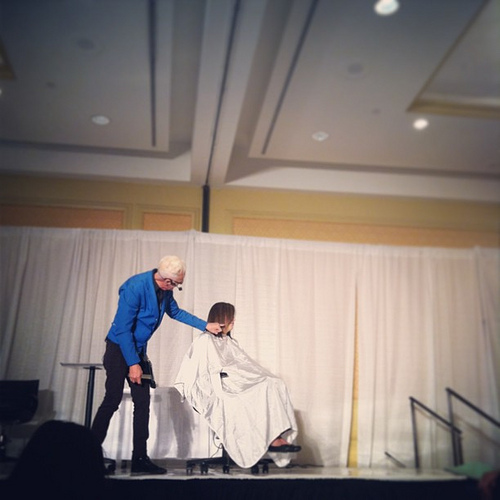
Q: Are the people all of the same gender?
A: No, they are both male and female.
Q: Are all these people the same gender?
A: No, they are both male and female.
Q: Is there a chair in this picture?
A: Yes, there is a chair.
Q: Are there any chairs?
A: Yes, there is a chair.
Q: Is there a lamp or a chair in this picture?
A: Yes, there is a chair.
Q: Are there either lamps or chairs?
A: Yes, there is a chair.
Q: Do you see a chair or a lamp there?
A: Yes, there is a chair.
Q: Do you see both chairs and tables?
A: Yes, there are both a chair and a table.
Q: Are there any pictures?
A: No, there are no pictures.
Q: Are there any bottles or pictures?
A: No, there are no pictures or bottles.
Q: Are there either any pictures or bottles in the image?
A: No, there are no pictures or bottles.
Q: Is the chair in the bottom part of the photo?
A: Yes, the chair is in the bottom of the image.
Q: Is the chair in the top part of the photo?
A: No, the chair is in the bottom of the image.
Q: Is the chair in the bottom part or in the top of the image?
A: The chair is in the bottom of the image.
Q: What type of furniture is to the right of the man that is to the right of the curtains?
A: The piece of furniture is a chair.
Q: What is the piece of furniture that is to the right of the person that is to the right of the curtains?
A: The piece of furniture is a chair.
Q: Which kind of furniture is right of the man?
A: The piece of furniture is a chair.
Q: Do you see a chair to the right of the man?
A: Yes, there is a chair to the right of the man.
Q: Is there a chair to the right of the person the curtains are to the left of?
A: Yes, there is a chair to the right of the man.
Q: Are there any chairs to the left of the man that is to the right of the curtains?
A: No, the chair is to the right of the man.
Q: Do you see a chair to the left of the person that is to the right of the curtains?
A: No, the chair is to the right of the man.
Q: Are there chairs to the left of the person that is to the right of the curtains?
A: No, the chair is to the right of the man.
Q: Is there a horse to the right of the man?
A: No, there is a chair to the right of the man.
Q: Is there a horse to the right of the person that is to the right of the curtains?
A: No, there is a chair to the right of the man.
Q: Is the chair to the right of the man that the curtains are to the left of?
A: Yes, the chair is to the right of the man.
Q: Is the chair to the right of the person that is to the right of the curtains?
A: Yes, the chair is to the right of the man.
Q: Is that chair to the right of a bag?
A: No, the chair is to the right of the man.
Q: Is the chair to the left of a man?
A: No, the chair is to the right of a man.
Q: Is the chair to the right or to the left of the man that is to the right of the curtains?
A: The chair is to the right of the man.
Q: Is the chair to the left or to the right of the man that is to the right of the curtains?
A: The chair is to the right of the man.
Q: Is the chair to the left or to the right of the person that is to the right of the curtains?
A: The chair is to the right of the man.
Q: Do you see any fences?
A: No, there are no fences.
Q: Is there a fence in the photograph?
A: No, there are no fences.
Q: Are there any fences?
A: No, there are no fences.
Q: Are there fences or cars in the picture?
A: No, there are no fences or cars.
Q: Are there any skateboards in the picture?
A: No, there are no skateboards.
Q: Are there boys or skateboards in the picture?
A: No, there are no skateboards or boys.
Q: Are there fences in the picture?
A: No, there are no fences.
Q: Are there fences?
A: No, there are no fences.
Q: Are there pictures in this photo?
A: No, there are no pictures.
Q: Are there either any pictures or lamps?
A: No, there are no pictures or lamps.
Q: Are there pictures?
A: No, there are no pictures.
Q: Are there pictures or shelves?
A: No, there are no pictures or shelves.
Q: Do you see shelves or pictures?
A: No, there are no pictures or shelves.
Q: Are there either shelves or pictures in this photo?
A: No, there are no pictures or shelves.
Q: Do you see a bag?
A: No, there are no bags.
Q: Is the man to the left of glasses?
A: No, the man is to the left of the draperies.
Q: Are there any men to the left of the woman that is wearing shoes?
A: Yes, there is a man to the left of the woman.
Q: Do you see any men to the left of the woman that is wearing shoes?
A: Yes, there is a man to the left of the woman.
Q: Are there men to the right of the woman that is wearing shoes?
A: No, the man is to the left of the woman.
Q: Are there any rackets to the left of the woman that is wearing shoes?
A: No, there is a man to the left of the woman.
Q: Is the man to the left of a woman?
A: Yes, the man is to the left of a woman.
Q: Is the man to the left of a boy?
A: No, the man is to the left of a woman.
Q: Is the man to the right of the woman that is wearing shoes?
A: No, the man is to the left of the woman.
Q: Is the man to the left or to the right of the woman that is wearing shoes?
A: The man is to the left of the woman.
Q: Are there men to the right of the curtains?
A: Yes, there is a man to the right of the curtains.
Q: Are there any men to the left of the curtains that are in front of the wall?
A: No, the man is to the right of the curtains.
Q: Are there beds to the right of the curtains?
A: No, there is a man to the right of the curtains.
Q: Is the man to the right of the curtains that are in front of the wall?
A: Yes, the man is to the right of the curtains.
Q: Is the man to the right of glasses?
A: No, the man is to the right of the curtains.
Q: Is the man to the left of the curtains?
A: No, the man is to the right of the curtains.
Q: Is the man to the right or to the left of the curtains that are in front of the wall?
A: The man is to the right of the curtains.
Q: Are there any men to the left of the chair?
A: Yes, there is a man to the left of the chair.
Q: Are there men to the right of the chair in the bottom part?
A: No, the man is to the left of the chair.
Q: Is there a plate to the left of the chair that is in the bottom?
A: No, there is a man to the left of the chair.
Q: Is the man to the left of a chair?
A: Yes, the man is to the left of a chair.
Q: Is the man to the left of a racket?
A: No, the man is to the left of a chair.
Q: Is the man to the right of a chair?
A: No, the man is to the left of a chair.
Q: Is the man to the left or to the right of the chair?
A: The man is to the left of the chair.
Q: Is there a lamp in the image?
A: No, there are no lamps.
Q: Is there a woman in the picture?
A: Yes, there is a woman.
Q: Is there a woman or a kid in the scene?
A: Yes, there is a woman.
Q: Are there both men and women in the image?
A: Yes, there are both a woman and a man.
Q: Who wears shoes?
A: The woman wears shoes.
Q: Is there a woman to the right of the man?
A: Yes, there is a woman to the right of the man.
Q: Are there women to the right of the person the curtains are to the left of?
A: Yes, there is a woman to the right of the man.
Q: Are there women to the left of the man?
A: No, the woman is to the right of the man.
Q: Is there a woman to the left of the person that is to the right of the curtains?
A: No, the woman is to the right of the man.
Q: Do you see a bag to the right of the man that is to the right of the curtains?
A: No, there is a woman to the right of the man.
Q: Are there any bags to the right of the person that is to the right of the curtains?
A: No, there is a woman to the right of the man.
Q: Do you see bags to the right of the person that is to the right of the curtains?
A: No, there is a woman to the right of the man.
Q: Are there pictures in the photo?
A: No, there are no pictures.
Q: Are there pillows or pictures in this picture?
A: No, there are no pictures or pillows.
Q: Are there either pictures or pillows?
A: No, there are no pictures or pillows.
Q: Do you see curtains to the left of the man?
A: Yes, there are curtains to the left of the man.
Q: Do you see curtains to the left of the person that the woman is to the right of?
A: Yes, there are curtains to the left of the man.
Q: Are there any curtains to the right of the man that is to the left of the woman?
A: No, the curtains are to the left of the man.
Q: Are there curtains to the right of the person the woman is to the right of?
A: No, the curtains are to the left of the man.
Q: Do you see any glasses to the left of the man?
A: No, there are curtains to the left of the man.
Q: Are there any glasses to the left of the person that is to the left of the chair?
A: No, there are curtains to the left of the man.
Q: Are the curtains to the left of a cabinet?
A: No, the curtains are to the left of a man.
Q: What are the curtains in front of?
A: The curtains are in front of the wall.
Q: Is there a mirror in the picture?
A: No, there are no mirrors.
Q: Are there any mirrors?
A: No, there are no mirrors.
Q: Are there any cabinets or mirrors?
A: No, there are no mirrors or cabinets.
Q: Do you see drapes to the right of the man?
A: Yes, there are drapes to the right of the man.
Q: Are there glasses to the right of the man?
A: No, there are drapes to the right of the man.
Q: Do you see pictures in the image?
A: No, there are no pictures.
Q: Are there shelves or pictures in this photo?
A: No, there are no pictures or shelves.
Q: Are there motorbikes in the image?
A: No, there are no motorbikes.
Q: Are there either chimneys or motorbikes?
A: No, there are no motorbikes or chimneys.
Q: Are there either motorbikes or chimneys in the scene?
A: No, there are no motorbikes or chimneys.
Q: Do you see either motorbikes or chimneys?
A: No, there are no motorbikes or chimneys.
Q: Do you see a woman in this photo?
A: Yes, there is a woman.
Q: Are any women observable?
A: Yes, there is a woman.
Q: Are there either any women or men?
A: Yes, there is a woman.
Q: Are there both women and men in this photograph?
A: Yes, there are both a woman and a man.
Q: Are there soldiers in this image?
A: No, there are no soldiers.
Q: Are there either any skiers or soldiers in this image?
A: No, there are no soldiers or skiers.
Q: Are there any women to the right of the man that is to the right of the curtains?
A: Yes, there is a woman to the right of the man.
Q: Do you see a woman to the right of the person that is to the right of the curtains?
A: Yes, there is a woman to the right of the man.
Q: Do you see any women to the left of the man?
A: No, the woman is to the right of the man.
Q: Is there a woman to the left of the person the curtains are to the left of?
A: No, the woman is to the right of the man.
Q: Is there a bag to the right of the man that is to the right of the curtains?
A: No, there is a woman to the right of the man.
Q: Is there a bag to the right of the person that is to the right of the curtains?
A: No, there is a woman to the right of the man.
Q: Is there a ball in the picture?
A: No, there are no balls.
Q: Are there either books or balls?
A: No, there are no balls or books.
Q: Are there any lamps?
A: No, there are no lamps.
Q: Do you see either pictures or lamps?
A: No, there are no lamps or pictures.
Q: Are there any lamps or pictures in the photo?
A: No, there are no lamps or pictures.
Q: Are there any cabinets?
A: No, there are no cabinets.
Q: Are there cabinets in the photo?
A: No, there are no cabinets.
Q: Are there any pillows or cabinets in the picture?
A: No, there are no cabinets or pillows.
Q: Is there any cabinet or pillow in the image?
A: No, there are no cabinets or pillows.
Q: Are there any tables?
A: Yes, there is a table.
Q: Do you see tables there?
A: Yes, there is a table.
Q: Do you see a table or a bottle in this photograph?
A: Yes, there is a table.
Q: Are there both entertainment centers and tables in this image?
A: No, there is a table but no entertainment centers.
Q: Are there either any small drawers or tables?
A: Yes, there is a small table.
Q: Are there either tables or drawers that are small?
A: Yes, the table is small.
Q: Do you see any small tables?
A: Yes, there is a small table.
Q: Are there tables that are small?
A: Yes, there is a table that is small.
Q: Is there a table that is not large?
A: Yes, there is a small table.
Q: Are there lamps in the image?
A: No, there are no lamps.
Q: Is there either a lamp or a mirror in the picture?
A: No, there are no lamps or mirrors.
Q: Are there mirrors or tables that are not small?
A: No, there is a table but it is small.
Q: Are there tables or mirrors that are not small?
A: No, there is a table but it is small.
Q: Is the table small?
A: Yes, the table is small.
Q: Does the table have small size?
A: Yes, the table is small.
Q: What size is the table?
A: The table is small.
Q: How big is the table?
A: The table is small.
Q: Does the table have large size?
A: No, the table is small.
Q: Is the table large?
A: No, the table is small.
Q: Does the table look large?
A: No, the table is small.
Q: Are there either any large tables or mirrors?
A: No, there is a table but it is small.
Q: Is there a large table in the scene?
A: No, there is a table but it is small.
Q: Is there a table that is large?
A: No, there is a table but it is small.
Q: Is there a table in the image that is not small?
A: No, there is a table but it is small.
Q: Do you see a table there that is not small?
A: No, there is a table but it is small.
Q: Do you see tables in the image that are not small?
A: No, there is a table but it is small.